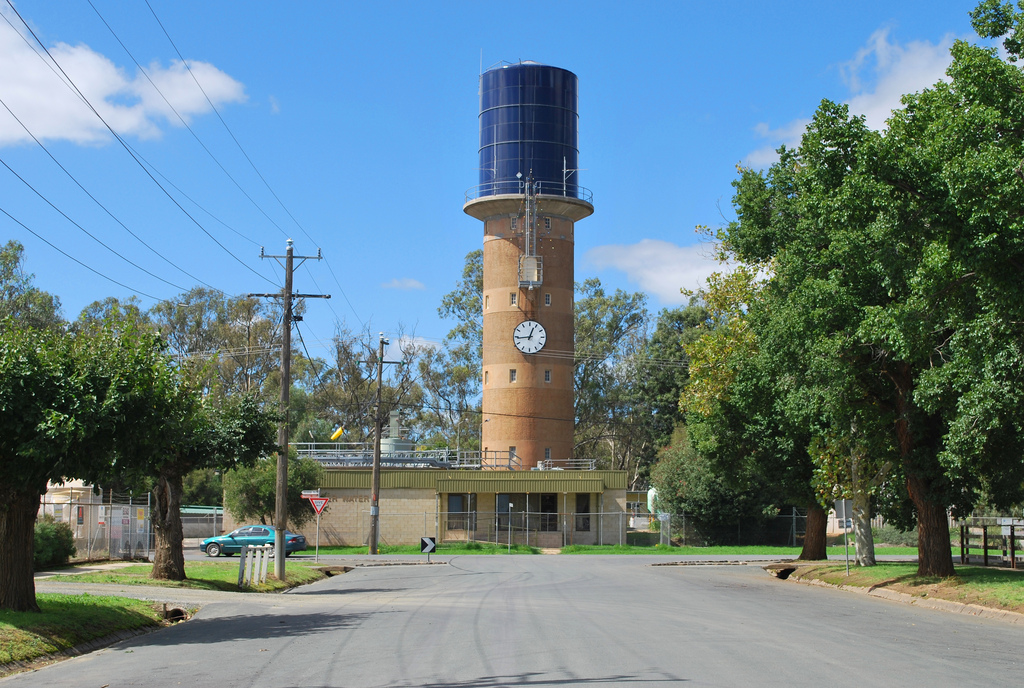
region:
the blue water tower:
[457, 45, 617, 213]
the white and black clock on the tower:
[510, 322, 569, 361]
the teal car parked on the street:
[203, 511, 305, 565]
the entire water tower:
[444, 47, 587, 472]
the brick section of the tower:
[459, 186, 595, 466]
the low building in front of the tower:
[209, 429, 637, 567]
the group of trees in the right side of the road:
[677, 95, 1020, 601]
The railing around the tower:
[453, 174, 619, 225]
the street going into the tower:
[19, 503, 1018, 685]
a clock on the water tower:
[508, 312, 551, 363]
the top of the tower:
[479, 54, 584, 188]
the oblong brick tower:
[467, 192, 598, 468]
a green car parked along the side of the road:
[198, 516, 309, 558]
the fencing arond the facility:
[37, 494, 692, 562]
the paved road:
[8, 549, 1023, 685]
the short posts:
[228, 537, 273, 585]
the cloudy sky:
[0, 7, 1022, 422]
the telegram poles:
[271, 234, 392, 577]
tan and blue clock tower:
[451, 46, 610, 476]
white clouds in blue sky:
[293, 129, 338, 169]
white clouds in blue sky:
[640, 230, 698, 282]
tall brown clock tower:
[436, 43, 629, 451]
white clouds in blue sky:
[50, 34, 142, 156]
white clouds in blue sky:
[24, 162, 98, 232]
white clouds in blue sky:
[173, 52, 269, 152]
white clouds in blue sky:
[607, 26, 699, 69]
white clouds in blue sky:
[621, 113, 673, 148]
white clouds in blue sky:
[581, 205, 668, 279]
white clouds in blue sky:
[691, 52, 778, 109]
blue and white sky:
[6, 36, 279, 107]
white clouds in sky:
[42, 5, 295, 162]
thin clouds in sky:
[1, 36, 273, 153]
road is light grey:
[367, 548, 598, 643]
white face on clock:
[500, 305, 554, 353]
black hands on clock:
[510, 319, 542, 348]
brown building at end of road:
[250, 429, 696, 572]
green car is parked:
[169, 518, 375, 557]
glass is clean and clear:
[541, 364, 552, 384]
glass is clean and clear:
[447, 493, 466, 531]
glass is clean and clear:
[503, 493, 523, 525]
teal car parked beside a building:
[196, 518, 305, 560]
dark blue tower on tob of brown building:
[474, 58, 577, 202]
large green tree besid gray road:
[727, 55, 1022, 583]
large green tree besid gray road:
[73, 317, 285, 583]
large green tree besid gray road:
[664, 270, 876, 565]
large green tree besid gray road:
[0, 243, 121, 620]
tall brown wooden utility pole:
[240, 236, 339, 581]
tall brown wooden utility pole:
[361, 328, 415, 554]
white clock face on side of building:
[511, 318, 549, 357]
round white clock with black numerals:
[511, 312, 547, 354]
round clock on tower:
[507, 310, 555, 364]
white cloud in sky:
[3, 18, 242, 171]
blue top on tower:
[463, 47, 618, 209]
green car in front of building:
[185, 514, 338, 579]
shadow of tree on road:
[15, 595, 360, 668]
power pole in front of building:
[333, 316, 422, 569]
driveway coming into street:
[40, 556, 339, 637]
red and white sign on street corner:
[292, 484, 346, 561]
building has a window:
[529, 487, 558, 507]